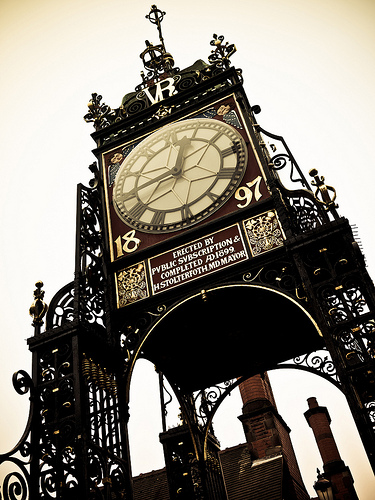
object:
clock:
[99, 96, 273, 263]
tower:
[0, 4, 375, 500]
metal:
[258, 122, 341, 235]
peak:
[146, 1, 167, 36]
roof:
[133, 443, 292, 500]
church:
[158, 363, 302, 498]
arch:
[121, 283, 330, 377]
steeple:
[235, 372, 276, 418]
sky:
[0, 1, 375, 183]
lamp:
[314, 467, 334, 499]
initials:
[142, 78, 178, 107]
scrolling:
[268, 153, 290, 172]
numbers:
[113, 227, 143, 257]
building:
[304, 391, 358, 497]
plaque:
[114, 207, 287, 311]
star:
[138, 142, 218, 207]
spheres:
[147, 7, 167, 27]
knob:
[201, 289, 208, 302]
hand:
[175, 135, 187, 170]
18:
[114, 229, 141, 258]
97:
[235, 175, 263, 209]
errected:
[173, 242, 203, 259]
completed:
[161, 259, 203, 280]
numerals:
[219, 145, 241, 158]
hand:
[115, 165, 174, 199]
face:
[114, 117, 248, 235]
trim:
[102, 83, 226, 147]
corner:
[230, 90, 236, 98]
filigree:
[83, 33, 237, 131]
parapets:
[83, 35, 246, 146]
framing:
[44, 84, 330, 333]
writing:
[150, 234, 246, 292]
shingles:
[235, 468, 278, 498]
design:
[136, 1, 175, 71]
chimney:
[306, 395, 319, 409]